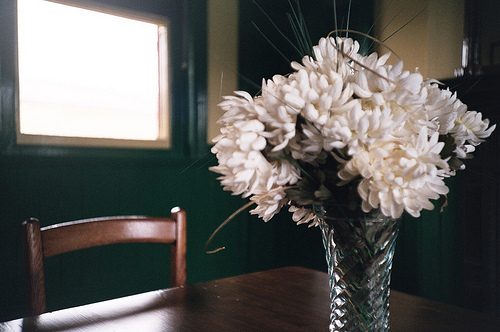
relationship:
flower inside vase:
[210, 38, 494, 231] [321, 215, 405, 327]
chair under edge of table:
[33, 196, 207, 311] [88, 218, 460, 318]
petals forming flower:
[404, 187, 419, 216] [207, 35, 497, 226]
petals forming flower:
[410, 157, 427, 172] [207, 35, 497, 226]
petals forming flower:
[373, 173, 384, 209] [207, 35, 497, 226]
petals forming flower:
[328, 105, 368, 125] [207, 35, 497, 226]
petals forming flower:
[370, 112, 405, 129] [207, 35, 497, 226]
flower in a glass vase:
[210, 38, 494, 231] [313, 211, 403, 327]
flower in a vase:
[210, 38, 494, 231] [310, 203, 397, 330]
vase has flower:
[310, 203, 397, 330] [210, 122, 267, 192]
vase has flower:
[310, 203, 397, 330] [252, 190, 283, 221]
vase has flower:
[310, 203, 397, 330] [366, 150, 449, 220]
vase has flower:
[310, 203, 397, 330] [284, 72, 355, 120]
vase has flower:
[310, 203, 397, 330] [459, 110, 494, 142]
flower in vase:
[210, 38, 494, 231] [313, 211, 403, 327]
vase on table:
[310, 203, 397, 330] [0, 263, 499, 329]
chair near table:
[22, 204, 190, 311] [0, 263, 499, 329]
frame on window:
[12, 0, 171, 146] [18, 0, 158, 140]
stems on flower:
[290, 158, 362, 217] [210, 38, 494, 231]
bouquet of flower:
[216, 35, 499, 217] [367, 151, 445, 212]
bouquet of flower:
[216, 35, 499, 217] [456, 111, 492, 146]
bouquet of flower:
[216, 35, 499, 217] [220, 92, 257, 122]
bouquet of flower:
[216, 35, 499, 217] [213, 151, 271, 197]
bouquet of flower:
[216, 35, 499, 217] [251, 189, 288, 220]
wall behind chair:
[4, 171, 216, 320] [10, 171, 175, 320]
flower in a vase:
[210, 38, 494, 231] [310, 186, 403, 328]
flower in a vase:
[442, 83, 494, 155] [310, 203, 397, 330]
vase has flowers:
[310, 203, 397, 330] [340, 147, 451, 214]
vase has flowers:
[310, 203, 397, 330] [429, 95, 496, 147]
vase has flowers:
[310, 203, 397, 330] [353, 55, 423, 112]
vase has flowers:
[310, 203, 397, 330] [271, 63, 358, 148]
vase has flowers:
[310, 203, 397, 330] [212, 110, 271, 193]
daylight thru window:
[31, 15, 155, 119] [13, 0, 169, 147]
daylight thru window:
[18, 15, 163, 139] [13, 0, 169, 147]